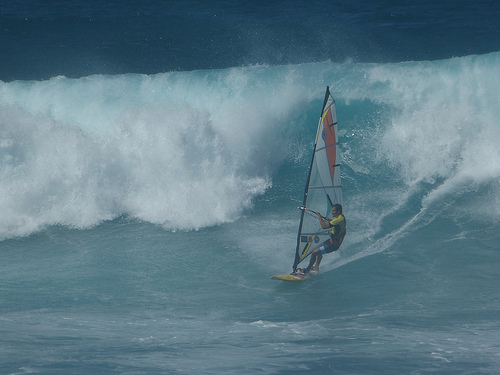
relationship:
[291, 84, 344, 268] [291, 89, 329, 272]
sail attached mast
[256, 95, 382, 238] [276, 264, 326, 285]
sail sticking out of board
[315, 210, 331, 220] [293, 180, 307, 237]
hands on pole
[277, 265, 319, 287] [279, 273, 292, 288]
feet on board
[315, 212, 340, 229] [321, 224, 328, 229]
arm bent at elbow